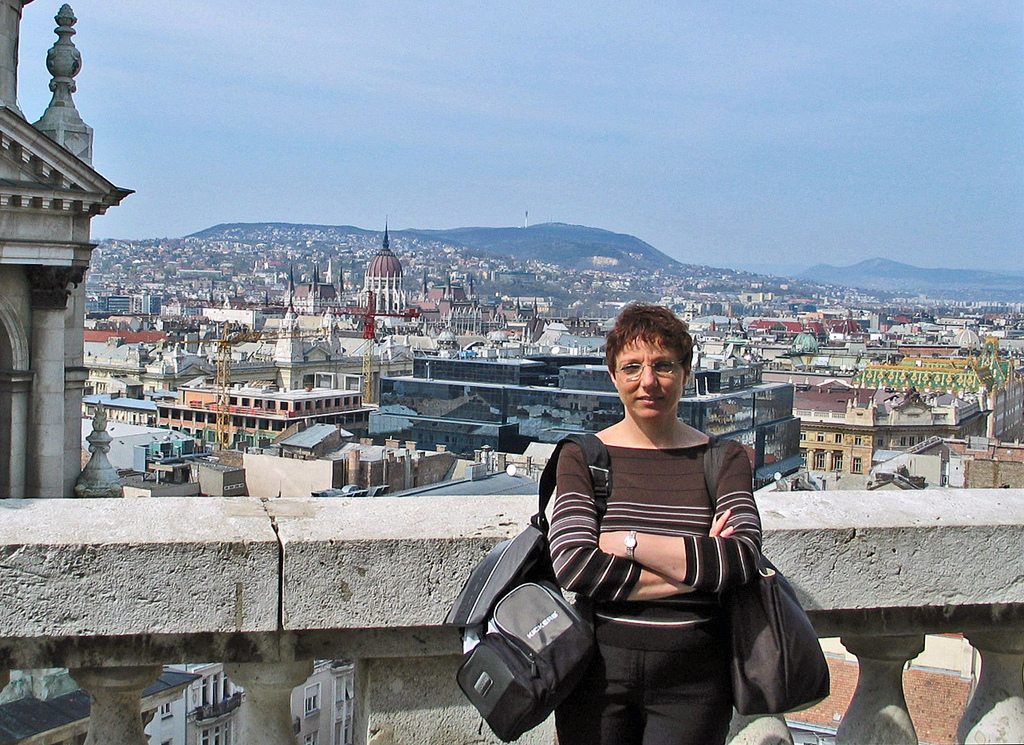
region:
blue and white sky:
[421, 50, 742, 181]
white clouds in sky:
[512, 82, 731, 178]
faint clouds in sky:
[348, 20, 564, 128]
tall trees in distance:
[465, 170, 681, 257]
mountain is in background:
[447, 199, 666, 298]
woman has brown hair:
[623, 269, 687, 342]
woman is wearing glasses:
[593, 374, 683, 397]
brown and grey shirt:
[456, 448, 783, 649]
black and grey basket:
[465, 550, 663, 681]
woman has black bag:
[658, 524, 851, 722]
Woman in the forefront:
[425, 297, 836, 743]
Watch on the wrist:
[618, 519, 644, 562]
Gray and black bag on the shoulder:
[444, 427, 635, 741]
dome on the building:
[359, 221, 407, 278]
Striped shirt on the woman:
[528, 279, 772, 647]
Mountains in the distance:
[179, 203, 1020, 301]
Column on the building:
[19, 262, 80, 496]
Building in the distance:
[362, 326, 814, 486]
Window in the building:
[810, 429, 830, 445]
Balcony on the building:
[190, 680, 251, 726]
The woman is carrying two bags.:
[439, 296, 828, 742]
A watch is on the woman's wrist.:
[615, 530, 657, 560]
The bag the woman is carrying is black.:
[704, 527, 834, 706]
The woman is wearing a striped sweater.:
[539, 418, 762, 653]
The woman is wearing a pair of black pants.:
[537, 629, 752, 743]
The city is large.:
[8, 211, 1023, 488]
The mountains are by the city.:
[27, 203, 1023, 293]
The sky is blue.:
[25, 6, 1022, 260]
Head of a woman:
[588, 300, 703, 441]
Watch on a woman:
[616, 519, 649, 568]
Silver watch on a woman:
[615, 521, 645, 570]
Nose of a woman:
[635, 363, 665, 396]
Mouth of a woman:
[631, 391, 676, 415]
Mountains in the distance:
[476, 203, 995, 301]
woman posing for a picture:
[465, 259, 842, 743]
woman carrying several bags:
[418, 268, 829, 724]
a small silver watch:
[598, 516, 652, 578]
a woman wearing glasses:
[589, 294, 720, 422]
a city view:
[48, 168, 990, 516]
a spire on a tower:
[345, 198, 426, 306]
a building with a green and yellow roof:
[839, 328, 1010, 399]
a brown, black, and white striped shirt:
[542, 414, 805, 643]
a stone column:
[14, 243, 100, 738]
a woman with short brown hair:
[547, 303, 762, 743]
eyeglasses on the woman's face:
[612, 353, 690, 382]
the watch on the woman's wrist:
[622, 527, 641, 562]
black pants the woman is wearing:
[555, 644, 736, 743]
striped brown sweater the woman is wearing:
[549, 433, 762, 655]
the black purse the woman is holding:
[727, 528, 832, 718]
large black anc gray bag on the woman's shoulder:
[448, 426, 611, 739]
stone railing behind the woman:
[2, 483, 1023, 743]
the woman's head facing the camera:
[604, 304, 693, 421]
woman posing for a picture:
[441, 285, 842, 741]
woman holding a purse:
[433, 285, 850, 741]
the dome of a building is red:
[357, 217, 419, 300]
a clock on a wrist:
[612, 515, 651, 565]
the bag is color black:
[723, 521, 847, 733]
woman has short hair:
[528, 281, 771, 559]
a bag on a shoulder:
[431, 419, 620, 740]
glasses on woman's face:
[607, 355, 684, 381]